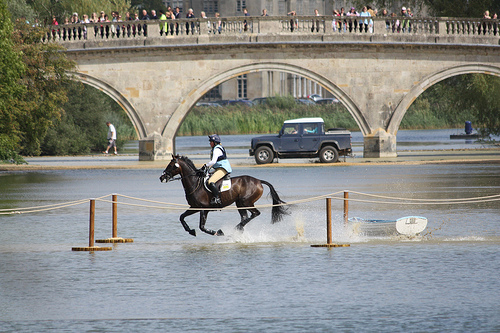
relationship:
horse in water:
[168, 153, 291, 235] [2, 166, 492, 327]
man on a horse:
[200, 133, 234, 200] [168, 153, 291, 235]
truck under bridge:
[251, 118, 355, 162] [13, 12, 496, 160]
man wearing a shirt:
[105, 121, 120, 151] [110, 127, 116, 137]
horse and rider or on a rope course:
[161, 133, 285, 239] [4, 193, 497, 250]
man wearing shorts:
[105, 121, 120, 151] [107, 137, 116, 145]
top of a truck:
[280, 114, 324, 124] [251, 118, 355, 162]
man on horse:
[200, 133, 234, 200] [168, 153, 291, 235]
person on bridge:
[397, 7, 416, 37] [13, 12, 496, 160]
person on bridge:
[288, 9, 302, 29] [13, 12, 496, 160]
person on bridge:
[481, 8, 495, 30] [13, 12, 496, 160]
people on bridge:
[6, 9, 499, 31] [13, 12, 496, 160]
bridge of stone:
[13, 12, 496, 160] [140, 133, 173, 159]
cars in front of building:
[194, 93, 346, 105] [139, 4, 437, 100]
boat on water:
[349, 211, 424, 235] [2, 166, 492, 327]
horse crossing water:
[168, 153, 291, 235] [2, 166, 492, 327]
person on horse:
[200, 133, 234, 200] [168, 153, 291, 235]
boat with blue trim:
[349, 211, 424, 235] [348, 214, 430, 225]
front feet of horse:
[183, 223, 228, 240] [168, 153, 291, 235]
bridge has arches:
[13, 12, 496, 160] [28, 67, 499, 149]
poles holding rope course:
[79, 193, 358, 256] [4, 193, 497, 250]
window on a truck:
[283, 121, 301, 134] [251, 118, 355, 162]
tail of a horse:
[259, 177, 288, 217] [168, 153, 291, 235]